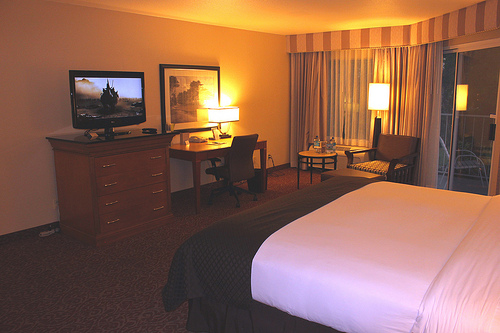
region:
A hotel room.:
[1, 1, 499, 331]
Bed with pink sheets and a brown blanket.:
[162, 172, 499, 332]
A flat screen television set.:
[69, 72, 146, 129]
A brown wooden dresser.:
[48, 134, 175, 251]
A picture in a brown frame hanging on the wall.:
[159, 62, 221, 132]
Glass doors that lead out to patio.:
[436, 37, 498, 192]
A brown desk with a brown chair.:
[167, 132, 269, 211]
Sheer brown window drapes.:
[289, 44, 441, 170]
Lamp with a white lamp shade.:
[368, 82, 390, 154]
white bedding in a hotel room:
[364, 198, 498, 329]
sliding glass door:
[437, 43, 497, 193]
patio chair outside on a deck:
[438, 137, 488, 189]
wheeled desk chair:
[207, 131, 257, 209]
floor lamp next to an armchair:
[345, 80, 422, 180]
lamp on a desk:
[173, 104, 269, 198]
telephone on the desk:
[183, 130, 213, 179]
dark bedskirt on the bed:
[189, 298, 251, 331]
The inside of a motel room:
[26, 15, 488, 315]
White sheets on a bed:
[276, 179, 487, 319]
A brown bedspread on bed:
[185, 177, 288, 294]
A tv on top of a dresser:
[58, 59, 157, 131]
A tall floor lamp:
[361, 74, 398, 141]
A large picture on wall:
[155, 55, 230, 133]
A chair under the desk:
[213, 128, 263, 186]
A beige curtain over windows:
[290, 42, 449, 157]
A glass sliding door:
[440, 45, 497, 184]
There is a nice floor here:
[106, 270, 120, 322]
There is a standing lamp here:
[361, 74, 385, 165]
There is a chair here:
[228, 128, 248, 190]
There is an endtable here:
[307, 143, 324, 203]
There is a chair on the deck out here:
[436, 133, 466, 224]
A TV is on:
[64, 67, 151, 128]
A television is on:
[60, 65, 155, 130]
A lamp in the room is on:
[363, 80, 393, 112]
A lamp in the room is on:
[193, 102, 243, 125]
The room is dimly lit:
[2, 1, 494, 328]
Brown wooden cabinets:
[57, 145, 176, 243]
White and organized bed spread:
[342, 204, 479, 308]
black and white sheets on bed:
[173, 173, 497, 332]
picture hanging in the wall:
[157, 59, 226, 129]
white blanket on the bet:
[251, 177, 498, 331]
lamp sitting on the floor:
[365, 80, 388, 158]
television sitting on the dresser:
[70, 69, 146, 142]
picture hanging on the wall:
[157, 63, 221, 134]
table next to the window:
[297, 143, 339, 185]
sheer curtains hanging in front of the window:
[330, 46, 406, 160]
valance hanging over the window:
[277, 2, 496, 56]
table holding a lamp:
[168, 134, 268, 205]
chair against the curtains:
[347, 131, 422, 187]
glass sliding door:
[447, 48, 497, 196]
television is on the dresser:
[66, 67, 148, 134]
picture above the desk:
[150, 58, 232, 135]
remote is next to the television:
[139, 122, 163, 136]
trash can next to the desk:
[246, 163, 276, 195]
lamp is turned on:
[362, 73, 395, 127]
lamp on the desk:
[205, 99, 246, 138]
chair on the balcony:
[437, 130, 488, 192]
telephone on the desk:
[186, 132, 208, 145]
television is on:
[68, 61, 146, 130]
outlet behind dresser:
[47, 191, 62, 218]